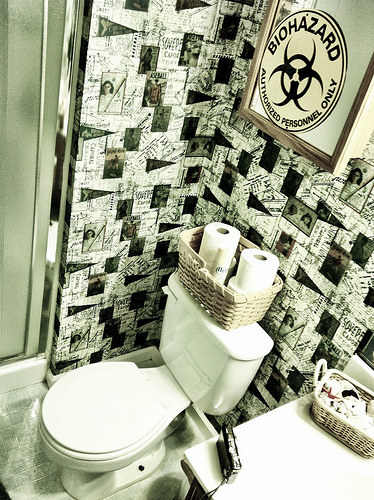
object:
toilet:
[37, 263, 275, 499]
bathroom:
[1, 0, 374, 499]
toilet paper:
[236, 245, 280, 294]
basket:
[177, 222, 283, 331]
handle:
[161, 285, 170, 298]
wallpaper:
[50, 0, 373, 418]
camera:
[216, 421, 242, 483]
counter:
[181, 352, 374, 499]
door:
[0, 1, 81, 367]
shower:
[0, 1, 86, 393]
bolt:
[138, 464, 145, 471]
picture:
[260, 8, 347, 132]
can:
[211, 247, 234, 285]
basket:
[311, 367, 373, 459]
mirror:
[236, 0, 373, 175]